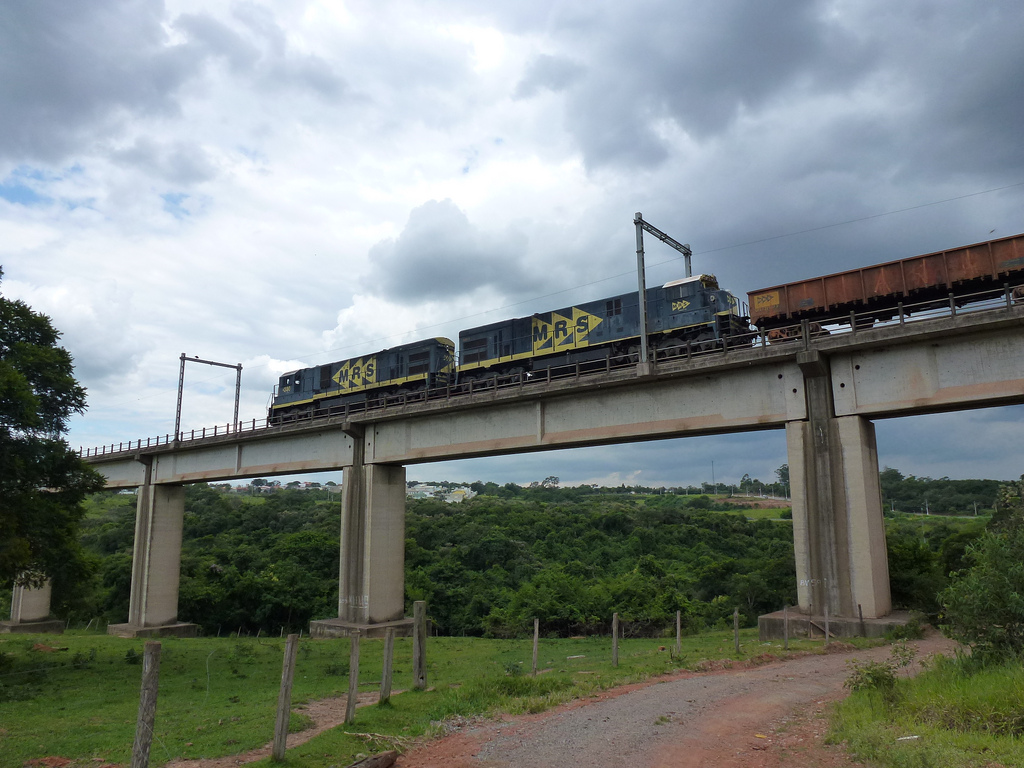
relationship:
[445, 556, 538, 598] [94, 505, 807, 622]
tree in woods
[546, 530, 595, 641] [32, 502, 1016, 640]
tree in woods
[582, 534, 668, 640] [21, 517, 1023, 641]
tree in woods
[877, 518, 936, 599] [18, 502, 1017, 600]
tree in woods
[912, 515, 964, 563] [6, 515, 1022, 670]
tree in woods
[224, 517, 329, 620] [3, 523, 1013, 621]
tree in woods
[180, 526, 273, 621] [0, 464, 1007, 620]
tree in woods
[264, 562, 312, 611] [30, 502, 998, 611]
tree in woods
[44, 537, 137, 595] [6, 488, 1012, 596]
tree in woods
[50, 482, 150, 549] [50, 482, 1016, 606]
tree in woods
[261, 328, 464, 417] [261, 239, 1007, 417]
locomotive of a train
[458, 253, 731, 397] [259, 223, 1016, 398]
locomotive of a train